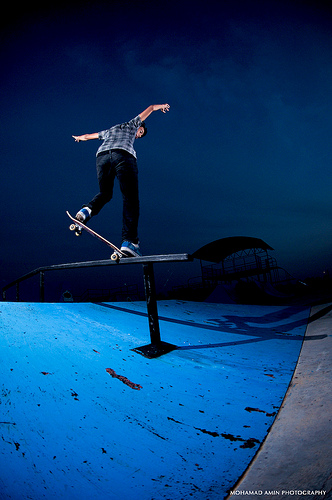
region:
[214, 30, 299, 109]
this is the sky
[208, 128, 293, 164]
the sky is blue in color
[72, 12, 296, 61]
the sky has clouds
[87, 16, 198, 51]
the clouds are white in color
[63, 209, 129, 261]
this is a surfboard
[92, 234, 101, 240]
the surfboard is wooden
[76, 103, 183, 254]
this is a man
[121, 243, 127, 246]
the shoe is blue in color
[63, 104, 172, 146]
the hands are stretched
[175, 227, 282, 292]
this is a shed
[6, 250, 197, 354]
a chipped black rail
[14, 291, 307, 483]
a bright blue ramp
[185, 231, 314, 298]
a simple covered platform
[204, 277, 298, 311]
a few concrete jumps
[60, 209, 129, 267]
a skateboard with small wheels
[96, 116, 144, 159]
a blue checkered shirt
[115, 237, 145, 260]
a bright blue shoe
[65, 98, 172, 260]
a young man skateboarding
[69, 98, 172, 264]
a skateboarder doing a trick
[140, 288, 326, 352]
a shadow on the ground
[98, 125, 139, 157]
The plaid shirt the skater is wearing.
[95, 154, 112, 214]
The left leg of the skater.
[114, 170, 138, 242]
The right leg of the skater.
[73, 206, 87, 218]
The left sneaker the skater is wearing.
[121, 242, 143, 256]
The right sneaker the skater is wearing.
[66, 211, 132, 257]
The skateboard the skater is riding.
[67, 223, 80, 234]
The back wheels of the skateboard.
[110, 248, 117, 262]
The front wheels of the skateboard.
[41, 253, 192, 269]
The railing the skater is on.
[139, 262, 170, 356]
The pole beneath the rail.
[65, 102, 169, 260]
the man on the skateboard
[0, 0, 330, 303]
the clouds in the dark blue sky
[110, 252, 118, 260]
the wheel on the skateboard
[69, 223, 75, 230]
the wheel on the skateboard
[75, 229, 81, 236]
the wheel on the skateboard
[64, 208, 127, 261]
the skateboard under the boy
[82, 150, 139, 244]
the long pants on the boy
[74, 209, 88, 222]
the shoe on the boy's foot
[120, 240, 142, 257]
the shoe on the boy's foot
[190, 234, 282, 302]
the structure in the background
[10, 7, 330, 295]
inky blue and clear night time sky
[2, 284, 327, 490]
aqua and grey skatboard ramp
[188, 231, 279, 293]
large covered open structure in background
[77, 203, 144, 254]
boy wearing bright blue tennis shoes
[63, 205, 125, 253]
black skateboard under boy's feet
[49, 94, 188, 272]
man performing balancing act with skateboard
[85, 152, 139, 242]
dark blue denim jeans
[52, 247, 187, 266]
platform and last chance to not jump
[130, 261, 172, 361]
heavy black metal pole with base for board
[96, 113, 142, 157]
boy in short sleeve plaid/checked shirt